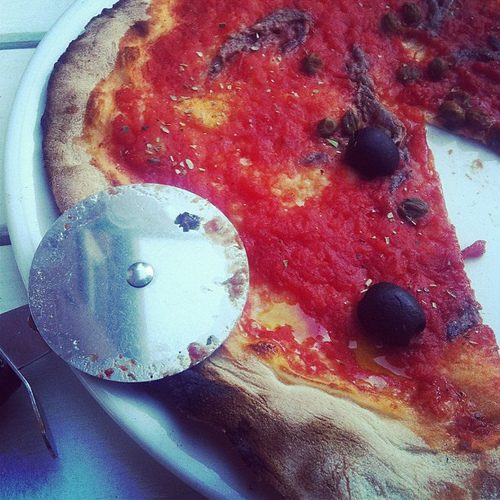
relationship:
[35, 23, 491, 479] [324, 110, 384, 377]
pita has olives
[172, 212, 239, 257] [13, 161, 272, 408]
grime on cutter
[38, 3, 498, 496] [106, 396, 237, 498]
food on plate